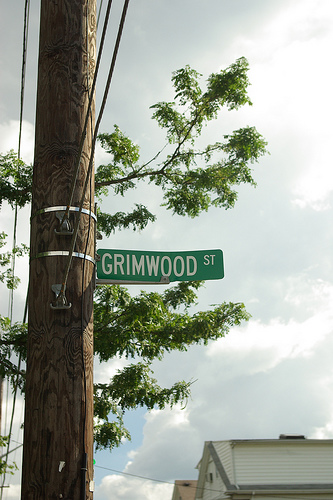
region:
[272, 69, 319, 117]
a white cloud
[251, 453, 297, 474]
the roof on the house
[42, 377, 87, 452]
a brown pole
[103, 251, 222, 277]
a green sign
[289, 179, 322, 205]
clouds in the sky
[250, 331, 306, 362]
a cloud in the sky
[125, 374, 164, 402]
the leaves are green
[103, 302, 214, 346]
branches and leaves of the tree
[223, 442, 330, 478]
roof of the building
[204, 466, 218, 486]
window of the building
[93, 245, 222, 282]
a street name board fixed in the tree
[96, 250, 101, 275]
bolts in the tree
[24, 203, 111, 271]
steel clamp fixed with the tree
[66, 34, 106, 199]
rope hanging near the tree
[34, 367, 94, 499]
a pole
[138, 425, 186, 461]
the cloud is white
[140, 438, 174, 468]
a white cloud in the sky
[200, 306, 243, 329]
the green leaves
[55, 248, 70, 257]
a metal clamp on the pole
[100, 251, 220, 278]
a street sign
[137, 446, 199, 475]
clouds are in the sky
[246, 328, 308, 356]
the white cloud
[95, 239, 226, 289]
Green sign on the pole.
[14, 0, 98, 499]
Telephone pole in the forefront.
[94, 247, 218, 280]
White lettering on the sign.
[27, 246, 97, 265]
Silver colored band on the pole.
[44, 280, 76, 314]
Latch on the pole.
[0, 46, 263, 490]
Tree in the background.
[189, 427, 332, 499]
House in the background.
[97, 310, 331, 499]
white cloud in the background.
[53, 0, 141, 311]
Cables on the pole.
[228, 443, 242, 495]
Gutter on the house.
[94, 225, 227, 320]
this is a street sign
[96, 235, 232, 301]
street sign is green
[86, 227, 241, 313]
white writing on sign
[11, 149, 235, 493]
street sign attached to post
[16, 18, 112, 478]
a brown street post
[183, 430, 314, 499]
top of a house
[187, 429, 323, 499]
top of house is white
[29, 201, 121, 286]
silver ring attachment for sign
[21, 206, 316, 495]
a bright and clear day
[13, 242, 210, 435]
green tree limbs behind post